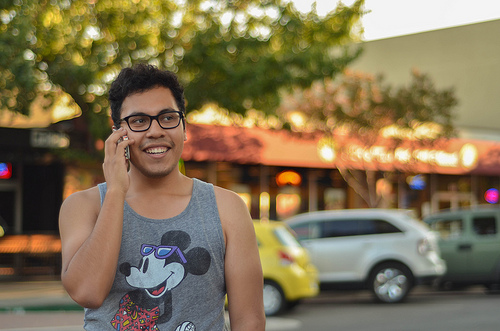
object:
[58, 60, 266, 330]
man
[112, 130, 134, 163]
cell phone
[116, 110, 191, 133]
glasses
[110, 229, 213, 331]
mickey mouse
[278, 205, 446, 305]
car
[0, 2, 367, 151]
tree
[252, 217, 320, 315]
car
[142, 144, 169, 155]
teeth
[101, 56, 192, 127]
hair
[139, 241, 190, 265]
sunglasses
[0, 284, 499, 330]
street